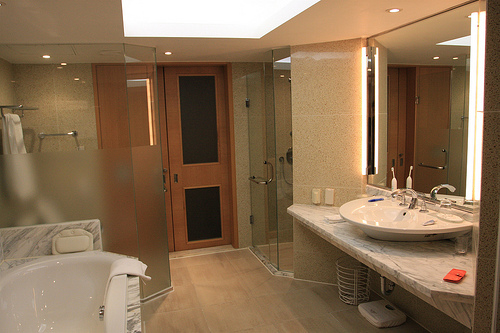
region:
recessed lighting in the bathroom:
[386, 5, 407, 19]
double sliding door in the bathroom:
[111, 59, 261, 264]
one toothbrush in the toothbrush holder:
[386, 160, 398, 195]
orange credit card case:
[436, 260, 468, 292]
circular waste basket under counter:
[330, 255, 370, 310]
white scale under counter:
[353, 292, 405, 331]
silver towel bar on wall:
[36, 120, 86, 148]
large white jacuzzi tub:
[4, 237, 159, 330]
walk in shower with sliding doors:
[231, 62, 301, 279]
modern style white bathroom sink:
[341, 182, 468, 249]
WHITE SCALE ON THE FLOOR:
[353, 293, 409, 329]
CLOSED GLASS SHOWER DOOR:
[240, 53, 297, 276]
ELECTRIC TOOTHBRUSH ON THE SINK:
[387, 165, 399, 195]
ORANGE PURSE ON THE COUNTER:
[441, 264, 467, 284]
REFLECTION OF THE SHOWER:
[389, 65, 463, 192]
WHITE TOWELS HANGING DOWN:
[3, 109, 35, 201]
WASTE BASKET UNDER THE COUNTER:
[333, 249, 370, 311]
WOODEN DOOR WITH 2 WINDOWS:
[166, 65, 241, 250]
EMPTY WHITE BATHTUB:
[8, 250, 144, 331]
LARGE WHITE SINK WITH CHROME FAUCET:
[336, 182, 471, 239]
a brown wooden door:
[152, 51, 252, 284]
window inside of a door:
[170, 66, 232, 176]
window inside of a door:
[179, 176, 226, 261]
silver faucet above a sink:
[380, 179, 440, 220]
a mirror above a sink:
[360, 1, 495, 206]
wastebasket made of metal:
[322, 238, 392, 319]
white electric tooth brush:
[382, 158, 409, 199]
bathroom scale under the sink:
[357, 278, 416, 332]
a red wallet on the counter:
[433, 259, 483, 294]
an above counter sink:
[323, 170, 475, 259]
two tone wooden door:
[163, 60, 243, 268]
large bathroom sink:
[340, 187, 463, 280]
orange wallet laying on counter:
[442, 258, 475, 310]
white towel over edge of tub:
[88, 250, 160, 311]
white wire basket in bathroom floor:
[327, 256, 377, 311]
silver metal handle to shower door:
[246, 157, 282, 197]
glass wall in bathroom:
[23, 41, 188, 248]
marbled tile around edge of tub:
[2, 225, 89, 271]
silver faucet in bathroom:
[383, 180, 444, 220]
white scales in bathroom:
[355, 294, 422, 331]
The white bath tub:
[5, 249, 130, 331]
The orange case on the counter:
[443, 264, 466, 284]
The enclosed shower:
[6, 41, 174, 306]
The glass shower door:
[125, 41, 175, 301]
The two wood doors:
[92, 60, 240, 257]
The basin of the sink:
[338, 193, 468, 240]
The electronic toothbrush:
[385, 165, 399, 195]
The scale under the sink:
[355, 292, 410, 329]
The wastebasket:
[331, 256, 376, 307]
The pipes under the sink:
[377, 271, 398, 297]